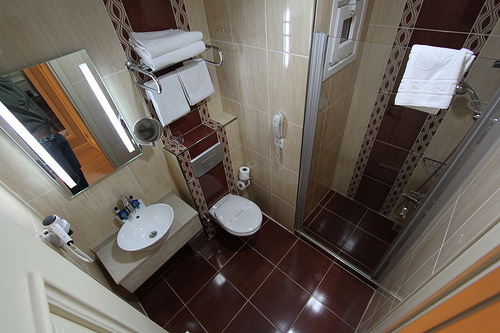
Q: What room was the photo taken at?
A: It was taken at the bathroom.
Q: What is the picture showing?
A: It is showing a bathroom.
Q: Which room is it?
A: It is a bathroom.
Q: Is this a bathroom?
A: Yes, it is a bathroom.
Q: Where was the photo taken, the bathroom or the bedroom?
A: It was taken at the bathroom.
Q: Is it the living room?
A: No, it is the bathroom.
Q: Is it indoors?
A: Yes, it is indoors.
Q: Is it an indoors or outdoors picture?
A: It is indoors.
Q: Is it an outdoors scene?
A: No, it is indoors.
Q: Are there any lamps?
A: No, there are no lamps.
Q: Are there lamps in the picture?
A: No, there are no lamps.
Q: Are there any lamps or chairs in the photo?
A: No, there are no lamps or chairs.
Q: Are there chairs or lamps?
A: No, there are no lamps or chairs.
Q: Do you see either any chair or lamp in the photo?
A: No, there are no lamps or chairs.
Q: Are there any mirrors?
A: Yes, there is a mirror.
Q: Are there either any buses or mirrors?
A: Yes, there is a mirror.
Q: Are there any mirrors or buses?
A: Yes, there is a mirror.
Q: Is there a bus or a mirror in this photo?
A: Yes, there is a mirror.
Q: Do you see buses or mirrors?
A: Yes, there is a mirror.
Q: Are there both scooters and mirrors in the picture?
A: No, there is a mirror but no scooters.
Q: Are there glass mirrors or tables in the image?
A: Yes, there is a glass mirror.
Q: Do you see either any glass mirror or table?
A: Yes, there is a glass mirror.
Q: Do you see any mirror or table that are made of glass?
A: Yes, the mirror is made of glass.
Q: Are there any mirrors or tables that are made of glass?
A: Yes, the mirror is made of glass.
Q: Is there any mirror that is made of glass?
A: Yes, there is a mirror that is made of glass.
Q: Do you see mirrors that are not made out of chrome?
A: Yes, there is a mirror that is made of glass.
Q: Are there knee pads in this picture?
A: No, there are no knee pads.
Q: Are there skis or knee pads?
A: No, there are no knee pads or skis.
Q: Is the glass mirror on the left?
A: Yes, the mirror is on the left of the image.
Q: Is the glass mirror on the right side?
A: No, the mirror is on the left of the image.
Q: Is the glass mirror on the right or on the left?
A: The mirror is on the left of the image.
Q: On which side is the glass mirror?
A: The mirror is on the left of the image.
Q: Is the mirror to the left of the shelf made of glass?
A: Yes, the mirror is made of glass.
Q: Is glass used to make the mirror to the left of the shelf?
A: Yes, the mirror is made of glass.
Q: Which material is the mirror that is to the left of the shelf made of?
A: The mirror is made of glass.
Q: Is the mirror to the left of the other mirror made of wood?
A: No, the mirror is made of glass.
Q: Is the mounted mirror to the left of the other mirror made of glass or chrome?
A: The mirror is made of glass.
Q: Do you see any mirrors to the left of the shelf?
A: Yes, there is a mirror to the left of the shelf.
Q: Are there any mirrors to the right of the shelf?
A: No, the mirror is to the left of the shelf.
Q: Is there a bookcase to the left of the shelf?
A: No, there is a mirror to the left of the shelf.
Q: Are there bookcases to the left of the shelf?
A: No, there is a mirror to the left of the shelf.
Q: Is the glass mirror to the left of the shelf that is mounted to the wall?
A: Yes, the mirror is to the left of the shelf.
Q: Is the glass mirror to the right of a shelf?
A: No, the mirror is to the left of a shelf.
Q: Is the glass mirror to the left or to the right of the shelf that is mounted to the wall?
A: The mirror is to the left of the shelf.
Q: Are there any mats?
A: No, there are no mats.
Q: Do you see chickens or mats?
A: No, there are no mats or chickens.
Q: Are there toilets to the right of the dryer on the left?
A: Yes, there is a toilet to the right of the dryer.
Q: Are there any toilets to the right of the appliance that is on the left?
A: Yes, there is a toilet to the right of the dryer.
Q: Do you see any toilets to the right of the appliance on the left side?
A: Yes, there is a toilet to the right of the dryer.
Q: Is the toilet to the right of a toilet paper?
A: No, the toilet is to the right of a dryer.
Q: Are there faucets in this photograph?
A: No, there are no faucets.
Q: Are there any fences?
A: No, there are no fences.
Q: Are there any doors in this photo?
A: Yes, there is a door.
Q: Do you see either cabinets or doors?
A: Yes, there is a door.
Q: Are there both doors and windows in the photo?
A: No, there is a door but no windows.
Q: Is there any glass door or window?
A: Yes, there is a glass door.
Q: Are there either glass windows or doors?
A: Yes, there is a glass door.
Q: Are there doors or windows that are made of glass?
A: Yes, the door is made of glass.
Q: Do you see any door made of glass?
A: Yes, there is a door that is made of glass.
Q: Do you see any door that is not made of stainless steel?
A: Yes, there is a door that is made of glass.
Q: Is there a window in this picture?
A: No, there are no windows.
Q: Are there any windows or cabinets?
A: No, there are no windows or cabinets.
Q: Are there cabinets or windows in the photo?
A: No, there are no windows or cabinets.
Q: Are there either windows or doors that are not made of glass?
A: No, there is a door but it is made of glass.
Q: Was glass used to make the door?
A: Yes, the door is made of glass.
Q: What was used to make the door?
A: The door is made of glass.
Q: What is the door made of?
A: The door is made of glass.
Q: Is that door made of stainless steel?
A: No, the door is made of glass.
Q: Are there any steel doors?
A: No, there is a door but it is made of glass.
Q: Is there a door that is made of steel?
A: No, there is a door but it is made of glass.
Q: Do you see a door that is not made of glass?
A: No, there is a door but it is made of glass.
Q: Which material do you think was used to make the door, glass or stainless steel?
A: The door is made of glass.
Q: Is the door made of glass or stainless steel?
A: The door is made of glass.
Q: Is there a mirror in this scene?
A: Yes, there is a mirror.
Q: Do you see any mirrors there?
A: Yes, there is a mirror.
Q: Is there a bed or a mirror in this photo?
A: Yes, there is a mirror.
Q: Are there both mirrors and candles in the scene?
A: No, there is a mirror but no candles.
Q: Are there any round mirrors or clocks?
A: Yes, there is a round mirror.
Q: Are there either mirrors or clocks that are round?
A: Yes, the mirror is round.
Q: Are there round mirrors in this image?
A: Yes, there is a round mirror.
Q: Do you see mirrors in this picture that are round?
A: Yes, there is a mirror that is round.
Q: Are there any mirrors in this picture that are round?
A: Yes, there is a mirror that is round.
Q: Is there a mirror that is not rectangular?
A: Yes, there is a round mirror.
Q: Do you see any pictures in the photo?
A: No, there are no pictures.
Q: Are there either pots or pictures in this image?
A: No, there are no pictures or pots.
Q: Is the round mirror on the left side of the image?
A: Yes, the mirror is on the left of the image.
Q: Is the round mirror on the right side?
A: No, the mirror is on the left of the image.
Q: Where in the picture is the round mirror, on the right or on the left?
A: The mirror is on the left of the image.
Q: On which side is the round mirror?
A: The mirror is on the left of the image.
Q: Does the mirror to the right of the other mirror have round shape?
A: Yes, the mirror is round.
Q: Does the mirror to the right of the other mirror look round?
A: Yes, the mirror is round.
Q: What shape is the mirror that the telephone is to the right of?
A: The mirror is round.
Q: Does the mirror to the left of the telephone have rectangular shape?
A: No, the mirror is round.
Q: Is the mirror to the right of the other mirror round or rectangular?
A: The mirror is round.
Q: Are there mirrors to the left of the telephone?
A: Yes, there is a mirror to the left of the telephone.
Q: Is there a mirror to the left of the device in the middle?
A: Yes, there is a mirror to the left of the telephone.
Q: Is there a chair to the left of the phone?
A: No, there is a mirror to the left of the phone.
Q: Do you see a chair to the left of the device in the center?
A: No, there is a mirror to the left of the phone.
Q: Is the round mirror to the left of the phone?
A: Yes, the mirror is to the left of the phone.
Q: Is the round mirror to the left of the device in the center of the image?
A: Yes, the mirror is to the left of the phone.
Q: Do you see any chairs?
A: No, there are no chairs.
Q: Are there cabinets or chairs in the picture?
A: No, there are no chairs or cabinets.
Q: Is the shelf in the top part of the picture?
A: Yes, the shelf is in the top of the image.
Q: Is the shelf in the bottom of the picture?
A: No, the shelf is in the top of the image.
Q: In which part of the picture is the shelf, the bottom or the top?
A: The shelf is in the top of the image.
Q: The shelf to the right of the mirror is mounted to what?
A: The shelf is mounted to the wall.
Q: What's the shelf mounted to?
A: The shelf is mounted to the wall.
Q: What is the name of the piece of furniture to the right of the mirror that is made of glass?
A: The piece of furniture is a shelf.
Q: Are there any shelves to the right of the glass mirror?
A: Yes, there is a shelf to the right of the mirror.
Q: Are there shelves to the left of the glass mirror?
A: No, the shelf is to the right of the mirror.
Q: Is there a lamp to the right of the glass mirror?
A: No, there is a shelf to the right of the mirror.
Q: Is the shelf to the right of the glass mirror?
A: Yes, the shelf is to the right of the mirror.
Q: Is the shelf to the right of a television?
A: No, the shelf is to the right of the mirror.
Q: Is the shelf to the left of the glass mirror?
A: No, the shelf is to the right of the mirror.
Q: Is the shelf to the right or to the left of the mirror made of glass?
A: The shelf is to the right of the mirror.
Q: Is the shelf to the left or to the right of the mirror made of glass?
A: The shelf is to the right of the mirror.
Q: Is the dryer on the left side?
A: Yes, the dryer is on the left of the image.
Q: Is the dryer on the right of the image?
A: No, the dryer is on the left of the image.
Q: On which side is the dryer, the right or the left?
A: The dryer is on the left of the image.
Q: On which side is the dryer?
A: The dryer is on the left of the image.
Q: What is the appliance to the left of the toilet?
A: The appliance is a dryer.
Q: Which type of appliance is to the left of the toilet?
A: The appliance is a dryer.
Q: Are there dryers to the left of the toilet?
A: Yes, there is a dryer to the left of the toilet.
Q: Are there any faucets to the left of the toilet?
A: No, there is a dryer to the left of the toilet.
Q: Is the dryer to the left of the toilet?
A: Yes, the dryer is to the left of the toilet.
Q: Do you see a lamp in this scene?
A: No, there are no lamps.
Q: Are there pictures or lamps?
A: No, there are no lamps or pictures.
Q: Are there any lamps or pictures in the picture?
A: No, there are no lamps or pictures.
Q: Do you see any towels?
A: Yes, there is a towel.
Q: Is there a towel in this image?
A: Yes, there is a towel.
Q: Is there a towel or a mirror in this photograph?
A: Yes, there is a towel.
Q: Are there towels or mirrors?
A: Yes, there is a towel.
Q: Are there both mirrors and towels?
A: Yes, there are both a towel and a mirror.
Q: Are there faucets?
A: No, there are no faucets.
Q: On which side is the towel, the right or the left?
A: The towel is on the right of the image.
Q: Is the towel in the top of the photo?
A: Yes, the towel is in the top of the image.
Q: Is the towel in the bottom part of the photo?
A: No, the towel is in the top of the image.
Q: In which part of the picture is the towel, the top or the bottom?
A: The towel is in the top of the image.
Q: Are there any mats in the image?
A: No, there are no mats.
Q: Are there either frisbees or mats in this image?
A: No, there are no mats or frisbees.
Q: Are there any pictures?
A: No, there are no pictures.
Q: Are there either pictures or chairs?
A: No, there are no pictures or chairs.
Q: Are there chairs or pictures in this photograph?
A: No, there are no pictures or chairs.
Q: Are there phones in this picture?
A: Yes, there is a phone.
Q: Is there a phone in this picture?
A: Yes, there is a phone.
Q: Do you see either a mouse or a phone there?
A: Yes, there is a phone.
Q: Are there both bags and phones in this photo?
A: No, there is a phone but no bags.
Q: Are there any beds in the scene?
A: No, there are no beds.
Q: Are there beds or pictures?
A: No, there are no beds or pictures.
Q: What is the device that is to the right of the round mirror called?
A: The device is a phone.